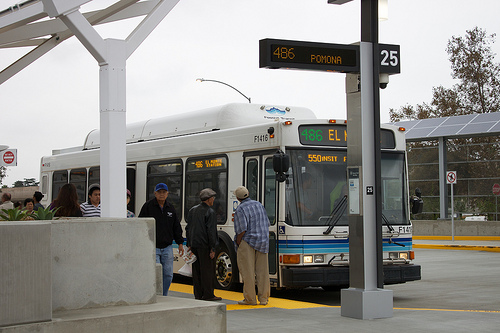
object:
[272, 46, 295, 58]
486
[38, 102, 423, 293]
bus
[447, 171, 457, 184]
sign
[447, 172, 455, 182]
do not enter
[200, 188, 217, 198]
hats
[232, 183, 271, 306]
man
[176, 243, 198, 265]
newspaper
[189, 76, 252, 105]
streetlight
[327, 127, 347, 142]
el monte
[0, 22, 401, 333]
station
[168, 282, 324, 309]
line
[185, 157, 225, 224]
windows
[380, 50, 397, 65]
numbers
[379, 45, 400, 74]
signboard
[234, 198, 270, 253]
shirt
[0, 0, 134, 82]
roof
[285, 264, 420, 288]
bumper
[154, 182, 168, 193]
hat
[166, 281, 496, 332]
sidewalk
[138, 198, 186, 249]
jacket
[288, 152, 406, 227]
windshield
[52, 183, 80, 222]
hair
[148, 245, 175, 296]
jeans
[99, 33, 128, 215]
support beam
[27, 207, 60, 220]
plants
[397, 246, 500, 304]
street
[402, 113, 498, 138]
solar panels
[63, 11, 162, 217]
pillar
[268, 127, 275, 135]
light cover